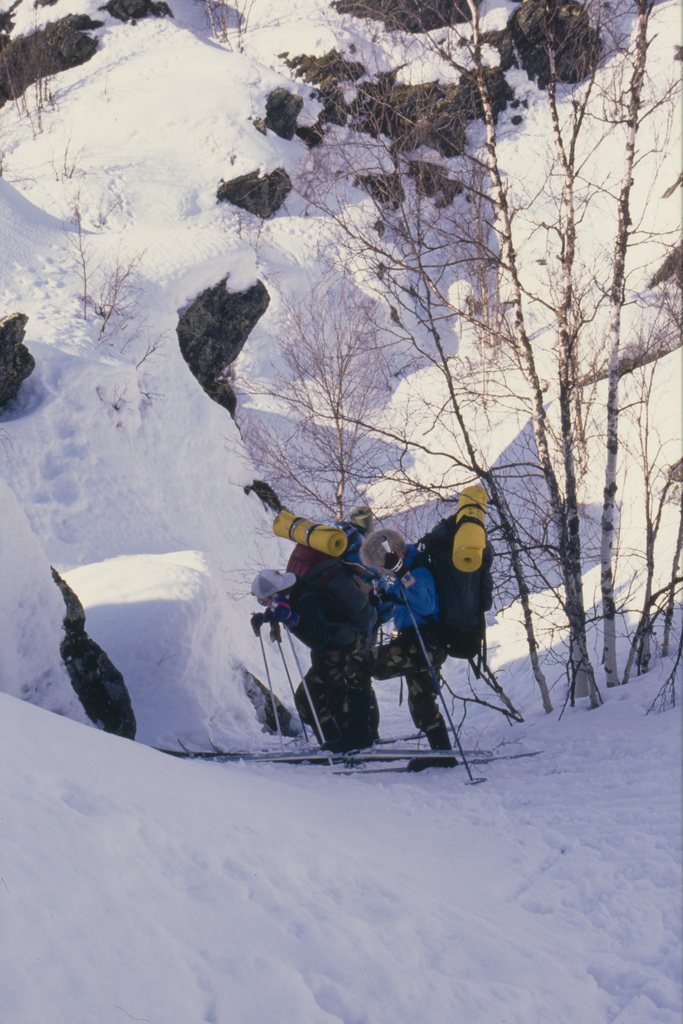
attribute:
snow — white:
[133, 784, 429, 869]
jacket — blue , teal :
[371, 556, 449, 641]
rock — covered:
[268, 85, 457, 200]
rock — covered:
[202, 272, 297, 365]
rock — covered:
[503, 9, 639, 92]